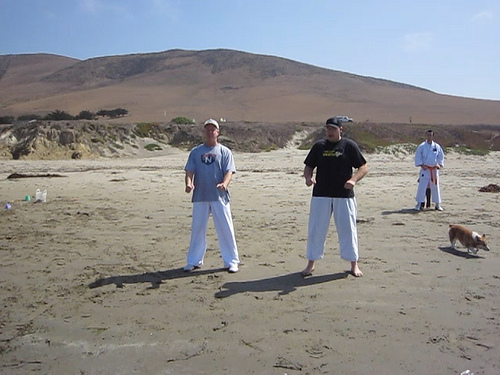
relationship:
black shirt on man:
[300, 138, 367, 198] [298, 117, 370, 279]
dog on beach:
[446, 223, 492, 256] [1, 151, 497, 373]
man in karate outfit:
[410, 128, 443, 208] [406, 139, 472, 227]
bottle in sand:
[36, 188, 42, 202] [2, 150, 483, 371]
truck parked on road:
[327, 115, 352, 125] [6, 109, 498, 128]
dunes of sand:
[28, 121, 175, 167] [7, 27, 495, 154]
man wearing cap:
[301, 116, 369, 277] [316, 112, 355, 131]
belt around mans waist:
[417, 159, 442, 176] [412, 163, 462, 182]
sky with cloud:
[0, 0, 499, 100] [403, 29, 439, 49]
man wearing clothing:
[415, 128, 445, 211] [415, 139, 445, 208]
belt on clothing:
[417, 163, 441, 183] [412, 139, 446, 206]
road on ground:
[0, 159, 496, 175] [0, 150, 497, 372]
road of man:
[0, 159, 496, 175] [301, 116, 369, 277]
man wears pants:
[301, 116, 369, 277] [295, 189, 372, 290]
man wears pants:
[183, 119, 240, 273] [184, 190, 239, 270]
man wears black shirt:
[301, 116, 369, 277] [300, 138, 367, 198]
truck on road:
[327, 110, 360, 132] [82, 110, 481, 130]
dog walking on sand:
[446, 223, 492, 256] [2, 150, 483, 371]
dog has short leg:
[445, 220, 493, 264] [444, 235, 461, 249]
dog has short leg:
[445, 220, 493, 264] [462, 243, 478, 258]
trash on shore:
[4, 183, 49, 215] [5, 160, 451, 365]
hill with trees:
[0, 47, 498, 129] [44, 105, 131, 127]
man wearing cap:
[294, 109, 373, 285] [321, 113, 347, 130]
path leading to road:
[280, 121, 312, 153] [0, 159, 496, 172]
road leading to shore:
[0, 159, 496, 172] [4, 137, 497, 157]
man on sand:
[183, 119, 240, 273] [331, 266, 471, 345]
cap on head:
[323, 117, 342, 128] [323, 125, 341, 142]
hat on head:
[196, 117, 230, 129] [193, 118, 223, 149]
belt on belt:
[417, 163, 441, 183] [417, 163, 441, 183]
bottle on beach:
[42, 189, 47, 203] [0, 117, 498, 368]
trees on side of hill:
[2, 107, 128, 124] [3, 47, 498, 129]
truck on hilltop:
[327, 115, 352, 125] [40, 32, 470, 164]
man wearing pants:
[99, 85, 296, 285] [148, 187, 265, 258]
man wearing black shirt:
[301, 116, 369, 277] [281, 136, 375, 181]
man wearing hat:
[301, 116, 369, 277] [317, 110, 349, 132]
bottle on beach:
[33, 187, 44, 202] [0, 142, 500, 375]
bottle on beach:
[40, 188, 48, 204] [0, 142, 500, 375]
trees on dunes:
[0, 106, 130, 126] [28, 121, 169, 160]